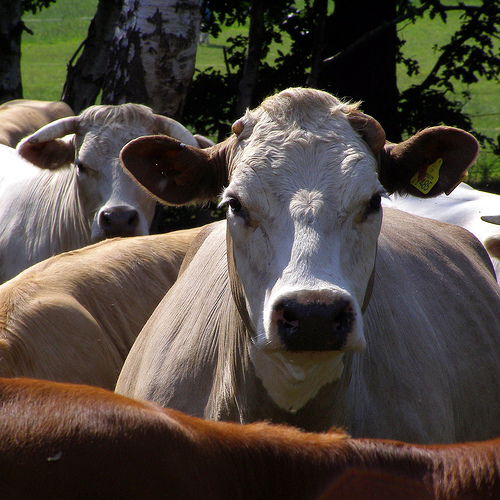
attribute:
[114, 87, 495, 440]
cow — white, facing camera, brown, tan, seeing camera, looking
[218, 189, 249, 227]
eye — soulful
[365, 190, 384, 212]
eye — soulful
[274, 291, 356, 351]
nose — wet, big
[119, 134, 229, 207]
ear — sticking out, funny, brown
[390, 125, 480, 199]
ear — sticking out, funny, brown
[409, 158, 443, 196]
tag — yellow, for tracking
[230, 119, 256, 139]
horn — removed, stump, nub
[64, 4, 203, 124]
trunk — in background, from tree, birch, part of tree, white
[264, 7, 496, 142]
tree — in silhouette, in background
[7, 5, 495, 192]
field — covered in grass, in background, grassy, green, in the distance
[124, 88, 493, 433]
fur — brown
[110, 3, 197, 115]
bark — birch, white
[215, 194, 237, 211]
lashes — long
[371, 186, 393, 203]
lashes — long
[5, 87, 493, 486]
cows — a bunch, together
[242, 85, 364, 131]
hair — soft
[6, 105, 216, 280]
cow — facing camera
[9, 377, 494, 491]
cow — brown, partially shown